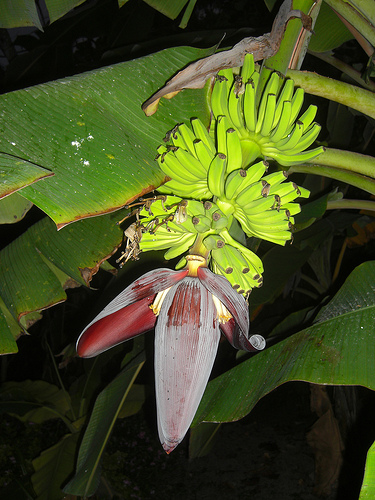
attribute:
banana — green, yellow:
[258, 93, 277, 138]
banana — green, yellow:
[204, 153, 230, 198]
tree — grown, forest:
[2, 1, 373, 499]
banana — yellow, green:
[210, 73, 226, 120]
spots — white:
[13, 117, 112, 178]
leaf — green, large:
[0, 34, 221, 235]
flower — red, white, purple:
[73, 255, 269, 447]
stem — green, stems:
[160, 2, 322, 263]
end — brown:
[239, 168, 246, 177]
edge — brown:
[55, 174, 170, 232]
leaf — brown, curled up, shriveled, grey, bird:
[141, 0, 314, 122]